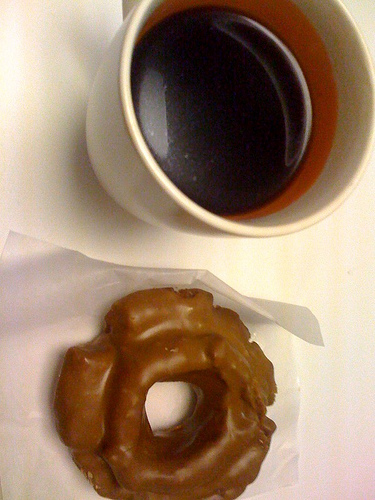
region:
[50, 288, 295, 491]
maple glazed cake doughnut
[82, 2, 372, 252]
white ceramic mug of coffee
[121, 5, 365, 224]
inside of coffee stained mug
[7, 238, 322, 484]
white wax paper with doughnut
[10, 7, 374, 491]
white counter with coffee cup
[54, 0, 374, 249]
white mug with coffee inside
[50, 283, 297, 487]
glazed brown cake doughnut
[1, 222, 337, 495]
white paper with glazed doughnut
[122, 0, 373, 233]
coffee stains on inside of cup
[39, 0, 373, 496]
cup with coffee and doughnut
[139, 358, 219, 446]
hole in middle of cake doughnut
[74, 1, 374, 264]
white ceramic coffee mug with handle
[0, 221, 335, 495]
doughnut served on white wax paper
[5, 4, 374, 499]
white counter under doughnut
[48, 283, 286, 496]
shiny doughnut frosted with maple frosting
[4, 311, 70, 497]
the paper is white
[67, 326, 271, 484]
the donut is chocolate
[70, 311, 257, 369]
notches in the donut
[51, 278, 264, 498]
donut on the paper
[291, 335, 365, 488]
the table is white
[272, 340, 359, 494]
paper on the table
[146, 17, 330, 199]
the coffee is black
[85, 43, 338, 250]
coffee in the mug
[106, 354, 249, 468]
hole in the donut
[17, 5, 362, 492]
beverage next to doughnut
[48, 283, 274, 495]
doughnut with chocolate glaze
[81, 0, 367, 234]
white cup with dark liquid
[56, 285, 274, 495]
hole in middle of doughnut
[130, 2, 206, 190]
oily speckles on surface of beverage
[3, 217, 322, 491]
curled edge of white waxed paper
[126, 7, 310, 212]
black opaque liquid in cup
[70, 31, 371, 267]
a mug of cofee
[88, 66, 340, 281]
coffee in a white mug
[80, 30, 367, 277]
coffee on a table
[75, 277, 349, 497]
a donut on a paper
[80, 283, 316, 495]
a glazed donut on table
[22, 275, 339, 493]
a table with donut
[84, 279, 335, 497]
a table with round donut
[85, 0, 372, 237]
the cup is white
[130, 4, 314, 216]
the reflection on the liquid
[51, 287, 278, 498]
the donut has a hole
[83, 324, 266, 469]
hole in the donut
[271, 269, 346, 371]
corner of the paper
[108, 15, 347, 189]
liquid in the cup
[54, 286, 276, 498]
the donut is whole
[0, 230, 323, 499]
the wax paper is white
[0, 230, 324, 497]
the donut is on the wax paper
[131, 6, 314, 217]
the liquid is dark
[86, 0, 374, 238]
the liquid in the cup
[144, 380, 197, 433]
the hole is small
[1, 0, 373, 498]
the cup is next to the donut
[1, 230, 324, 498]
the donut is on the white wax paper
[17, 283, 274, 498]
A piece of food.